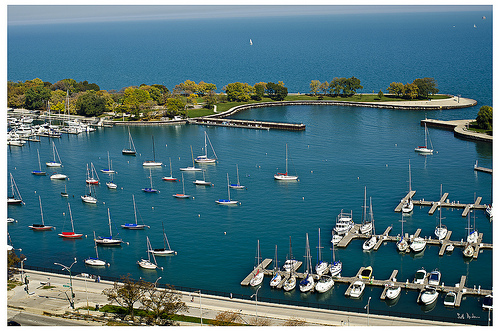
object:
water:
[4, 126, 492, 325]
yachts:
[60, 179, 70, 197]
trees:
[265, 79, 285, 100]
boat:
[407, 232, 429, 252]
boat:
[313, 273, 333, 294]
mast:
[420, 116, 438, 151]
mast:
[221, 170, 238, 200]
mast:
[101, 206, 112, 237]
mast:
[251, 236, 264, 271]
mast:
[123, 125, 137, 150]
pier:
[190, 116, 305, 132]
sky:
[52, 30, 123, 73]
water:
[5, 23, 488, 89]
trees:
[476, 106, 494, 130]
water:
[408, 94, 495, 131]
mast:
[180, 172, 191, 194]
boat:
[173, 172, 192, 198]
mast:
[284, 144, 288, 174]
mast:
[224, 172, 231, 199]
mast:
[66, 202, 75, 230]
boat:
[147, 222, 179, 256]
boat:
[28, 195, 53, 232]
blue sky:
[6, 5, 491, 27]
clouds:
[156, 24, 410, 138]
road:
[8, 264, 470, 325]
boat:
[213, 172, 239, 207]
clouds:
[404, 43, 454, 70]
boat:
[58, 200, 85, 238]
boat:
[271, 142, 298, 181]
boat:
[137, 233, 159, 269]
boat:
[333, 213, 354, 232]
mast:
[362, 186, 370, 222]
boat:
[141, 136, 162, 167]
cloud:
[8, 7, 485, 25]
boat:
[81, 229, 110, 268]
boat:
[120, 190, 151, 231]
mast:
[65, 199, 75, 233]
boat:
[248, 240, 265, 290]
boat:
[267, 240, 283, 287]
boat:
[296, 228, 315, 293]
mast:
[283, 143, 290, 176]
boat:
[412, 110, 437, 157]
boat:
[120, 120, 136, 157]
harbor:
[3, 84, 486, 322]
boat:
[248, 235, 264, 286]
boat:
[384, 281, 402, 301]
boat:
[416, 280, 440, 308]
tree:
[267, 81, 288, 101]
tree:
[309, 80, 321, 95]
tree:
[179, 79, 199, 98]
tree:
[387, 81, 405, 97]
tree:
[413, 77, 439, 100]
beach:
[366, 94, 476, 110]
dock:
[239, 256, 485, 306]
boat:
[346, 277, 366, 299]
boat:
[356, 262, 375, 282]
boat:
[409, 236, 427, 253]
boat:
[444, 242, 454, 252]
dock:
[335, 215, 485, 261]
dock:
[392, 185, 484, 215]